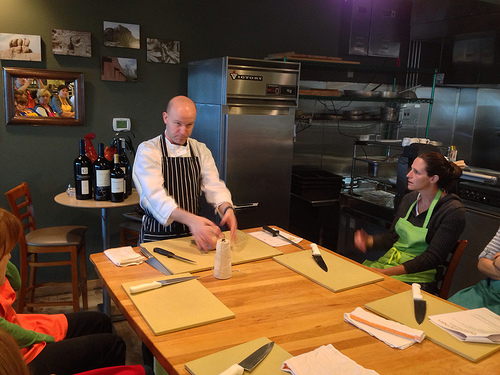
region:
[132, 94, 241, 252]
Bald man standing at the head of the table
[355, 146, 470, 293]
Woman in a green apron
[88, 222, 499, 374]
Dining table in the center of the room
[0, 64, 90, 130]
Photo of people in a wood frame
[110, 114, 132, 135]
White thermostat on the wall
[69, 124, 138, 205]
Alchohol bottles on the small table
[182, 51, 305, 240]
Stainless steel commercial fridge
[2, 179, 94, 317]
Empty chair to the left of the man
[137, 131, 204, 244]
Striped apron the man is wearing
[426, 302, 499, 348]
Papers stapled together on the table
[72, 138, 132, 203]
Bottles of fine wine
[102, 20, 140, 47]
Picture of a mountain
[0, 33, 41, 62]
Picture of a rock formation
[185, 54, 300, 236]
Commercial freezer in stainless steel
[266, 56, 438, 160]
Turquoise pot and pan shelving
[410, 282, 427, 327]
A white handled chef knife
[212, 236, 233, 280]
A roll of butchers twine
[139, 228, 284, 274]
A plastic cutting board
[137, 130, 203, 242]
A black and white striped apron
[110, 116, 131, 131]
A white wall mounted digital thermostat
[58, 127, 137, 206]
wine sits on the table behind the man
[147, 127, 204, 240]
he is wearing an apron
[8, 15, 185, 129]
several pictures hang on the wall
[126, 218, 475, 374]
many knives are out on the table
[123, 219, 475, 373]
cutting boards are out on the table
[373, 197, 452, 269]
the woman is wearing a green apron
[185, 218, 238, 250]
the man is handling meat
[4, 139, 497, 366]
people sit around the table watching the man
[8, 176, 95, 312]
a chair at the table behind the man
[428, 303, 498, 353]
some papers lay in front of this person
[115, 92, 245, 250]
man wearing an apron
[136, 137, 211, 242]
man's apron is striped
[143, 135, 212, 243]
apron is black and white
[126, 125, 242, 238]
man's shirt is white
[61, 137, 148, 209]
wine bottles behind the man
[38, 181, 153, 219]
table is circular shaped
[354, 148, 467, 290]
woman wearing an apron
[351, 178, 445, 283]
woman's apron is green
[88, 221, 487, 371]
knives laying on the table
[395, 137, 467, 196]
woman's hair in pony tail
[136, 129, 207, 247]
black and white striped apron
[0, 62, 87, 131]
photograph in brown wooden frame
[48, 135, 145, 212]
table top with bottles of wine sitting on it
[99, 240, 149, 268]
white folded towel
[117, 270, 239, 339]
tan cutting board with white handled knife on it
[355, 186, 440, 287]
green apron with yellow tie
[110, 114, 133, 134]
digital thermostat with white plastic framing it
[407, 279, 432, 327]
butcher knife with white plastic handle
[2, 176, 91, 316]
brown wooden table chair with tan seat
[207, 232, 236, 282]
large spindle of white string